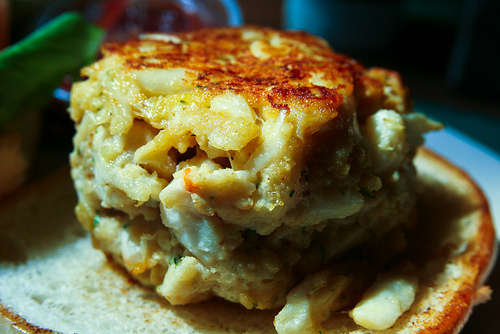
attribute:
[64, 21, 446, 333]
crab cake — spiced, cheesey, burnt, large, lumpy, fried, thick, herbed, food, cooked, food item, brown, oily, white, round, holey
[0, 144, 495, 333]
bread — burnt, toasted, brown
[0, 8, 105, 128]
napkin — green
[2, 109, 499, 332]
plate — blue, white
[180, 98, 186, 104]
spice — green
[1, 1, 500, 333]
picture — dark